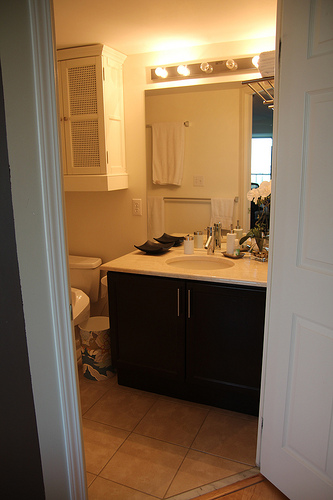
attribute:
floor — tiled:
[78, 372, 258, 497]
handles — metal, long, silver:
[177, 290, 192, 320]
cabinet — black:
[106, 274, 266, 417]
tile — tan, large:
[100, 434, 187, 499]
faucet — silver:
[202, 224, 214, 255]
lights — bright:
[152, 66, 192, 80]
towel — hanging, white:
[150, 123, 184, 190]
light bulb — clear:
[225, 60, 239, 74]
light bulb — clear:
[200, 62, 216, 78]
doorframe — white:
[255, 1, 329, 498]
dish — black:
[137, 241, 170, 255]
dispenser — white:
[223, 225, 237, 254]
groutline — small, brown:
[163, 450, 189, 499]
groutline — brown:
[95, 433, 131, 478]